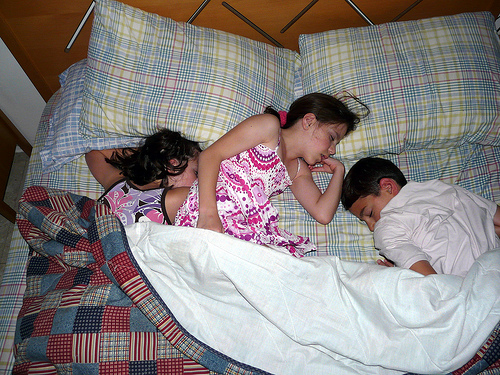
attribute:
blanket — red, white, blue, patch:
[13, 184, 498, 371]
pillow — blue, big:
[33, 45, 164, 165]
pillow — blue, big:
[81, 0, 295, 153]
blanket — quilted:
[11, 186, 343, 373]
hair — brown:
[106, 121, 199, 187]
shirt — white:
[388, 184, 486, 267]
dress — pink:
[171, 126, 319, 261]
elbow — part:
[299, 193, 344, 228]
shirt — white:
[371, 177, 497, 287]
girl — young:
[179, 78, 359, 285]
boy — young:
[339, 146, 493, 279]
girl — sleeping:
[73, 123, 193, 263]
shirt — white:
[374, 176, 499, 274]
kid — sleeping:
[339, 150, 499, 280]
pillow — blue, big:
[298, 13, 498, 156]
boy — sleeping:
[336, 154, 498, 278]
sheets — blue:
[23, 56, 480, 266]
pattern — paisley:
[175, 126, 318, 258]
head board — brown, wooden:
[1, 2, 498, 102]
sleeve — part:
[378, 227, 410, 261]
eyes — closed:
[364, 205, 375, 225]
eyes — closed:
[323, 130, 345, 142]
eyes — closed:
[190, 164, 207, 176]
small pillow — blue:
[37, 54, 144, 174]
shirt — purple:
[99, 167, 171, 223]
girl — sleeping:
[228, 72, 356, 226]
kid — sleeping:
[175, 89, 370, 259]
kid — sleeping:
[87, 125, 202, 224]